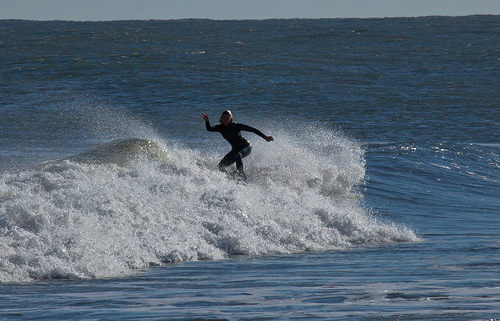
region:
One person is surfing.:
[164, 86, 284, 198]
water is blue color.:
[389, 169, 453, 293]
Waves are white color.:
[16, 173, 117, 266]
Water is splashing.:
[88, 98, 184, 175]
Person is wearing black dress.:
[202, 108, 272, 181]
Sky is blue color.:
[66, 2, 274, 20]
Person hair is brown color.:
[213, 109, 238, 125]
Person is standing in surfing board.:
[181, 95, 281, 195]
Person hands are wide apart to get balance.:
[188, 100, 278, 196]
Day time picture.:
[44, 49, 423, 239]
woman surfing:
[197, 102, 273, 182]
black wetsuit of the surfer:
[207, 123, 272, 172]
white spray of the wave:
[56, 83, 352, 145]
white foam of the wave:
[10, 154, 404, 281]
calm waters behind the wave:
[0, 21, 451, 135]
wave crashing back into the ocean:
[24, 180, 416, 289]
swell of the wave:
[367, 146, 498, 227]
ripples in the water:
[20, 223, 498, 310]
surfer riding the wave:
[200, 108, 275, 191]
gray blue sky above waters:
[7, 3, 499, 22]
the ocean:
[11, 20, 498, 318]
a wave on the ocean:
[26, 120, 476, 268]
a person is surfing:
[191, 102, 286, 189]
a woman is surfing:
[181, 97, 279, 189]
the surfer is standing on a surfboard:
[188, 105, 290, 202]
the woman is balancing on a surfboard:
[181, 103, 292, 199]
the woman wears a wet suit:
[196, 105, 288, 181]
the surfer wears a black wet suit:
[178, 98, 293, 200]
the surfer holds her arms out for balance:
[192, 100, 282, 191]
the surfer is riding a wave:
[58, 108, 385, 273]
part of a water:
[373, 44, 434, 104]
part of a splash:
[150, 175, 187, 213]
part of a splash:
[216, 200, 246, 235]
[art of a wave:
[391, 264, 428, 304]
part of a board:
[229, 168, 257, 205]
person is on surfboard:
[184, 108, 284, 188]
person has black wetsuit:
[198, 113, 250, 190]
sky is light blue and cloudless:
[151, 3, 282, 23]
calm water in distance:
[110, 25, 260, 105]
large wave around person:
[43, 150, 330, 266]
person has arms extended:
[210, 113, 305, 153]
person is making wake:
[57, 97, 182, 180]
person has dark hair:
[221, 100, 238, 120]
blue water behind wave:
[331, 130, 477, 257]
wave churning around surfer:
[38, 138, 365, 282]